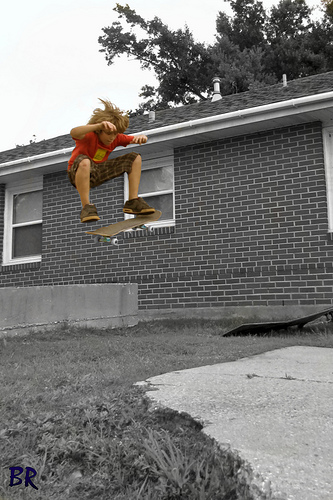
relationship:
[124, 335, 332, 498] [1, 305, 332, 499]
cement by grass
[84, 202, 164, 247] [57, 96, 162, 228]
skateboard under boy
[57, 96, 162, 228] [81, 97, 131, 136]
boy has hair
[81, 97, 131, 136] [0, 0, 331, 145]
hair in air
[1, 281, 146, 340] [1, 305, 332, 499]
wall in grass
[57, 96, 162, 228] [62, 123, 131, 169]
boy has shirt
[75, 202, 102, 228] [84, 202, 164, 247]
right foot on skateboard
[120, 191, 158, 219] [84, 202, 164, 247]
shoe on skateboard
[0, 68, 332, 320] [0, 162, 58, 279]
house has window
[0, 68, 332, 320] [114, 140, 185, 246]
house has window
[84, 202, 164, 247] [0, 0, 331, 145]
skateboard in air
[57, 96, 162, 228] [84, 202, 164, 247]
boy on skateboard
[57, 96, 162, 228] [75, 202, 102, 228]
boy has right foot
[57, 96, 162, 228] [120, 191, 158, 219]
boy has shoe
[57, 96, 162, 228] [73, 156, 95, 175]
boy has right knee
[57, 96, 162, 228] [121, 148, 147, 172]
boy has left knee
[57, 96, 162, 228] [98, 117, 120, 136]
boy has right hand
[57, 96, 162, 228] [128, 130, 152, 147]
boy has left hand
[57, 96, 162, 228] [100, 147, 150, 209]
boy has left leg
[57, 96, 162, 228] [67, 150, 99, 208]
boy has right leg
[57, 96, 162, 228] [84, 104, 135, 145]
boy has head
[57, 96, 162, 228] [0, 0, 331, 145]
boy in air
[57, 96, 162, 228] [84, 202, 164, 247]
boy performing on skateboard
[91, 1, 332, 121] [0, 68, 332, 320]
tree over house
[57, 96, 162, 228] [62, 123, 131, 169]
boy wearing shirt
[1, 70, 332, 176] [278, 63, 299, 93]
roof has vent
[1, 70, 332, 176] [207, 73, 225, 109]
roof has vent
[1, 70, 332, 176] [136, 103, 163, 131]
roof has vent